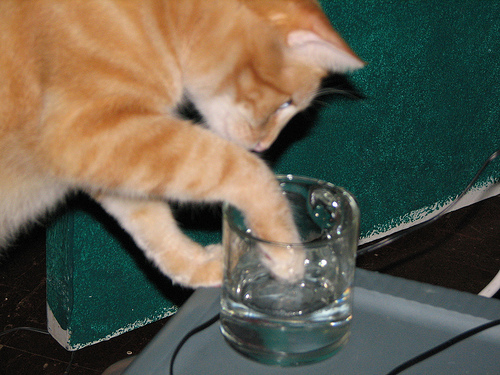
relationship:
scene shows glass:
[5, 7, 495, 372] [221, 174, 356, 364]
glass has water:
[221, 174, 356, 364] [231, 271, 348, 344]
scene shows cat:
[5, 7, 495, 372] [3, 2, 361, 289]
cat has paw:
[3, 2, 361, 289] [260, 239, 310, 286]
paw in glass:
[260, 239, 310, 286] [221, 174, 356, 364]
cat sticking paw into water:
[3, 2, 361, 289] [231, 271, 348, 344]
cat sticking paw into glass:
[3, 2, 361, 289] [221, 174, 356, 364]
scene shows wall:
[5, 7, 495, 372] [355, 16, 499, 234]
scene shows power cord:
[5, 7, 495, 372] [472, 269, 500, 297]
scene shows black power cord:
[5, 7, 495, 372] [168, 148, 496, 374]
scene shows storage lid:
[5, 7, 495, 372] [119, 251, 497, 371]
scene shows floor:
[5, 7, 495, 372] [363, 188, 499, 304]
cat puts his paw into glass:
[3, 2, 361, 289] [221, 174, 356, 364]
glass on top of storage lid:
[221, 174, 356, 364] [119, 251, 497, 371]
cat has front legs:
[3, 2, 361, 289] [84, 118, 308, 286]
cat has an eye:
[3, 2, 361, 289] [276, 98, 295, 111]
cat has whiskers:
[3, 2, 361, 289] [316, 84, 366, 112]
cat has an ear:
[3, 2, 361, 289] [289, 30, 364, 75]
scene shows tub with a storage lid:
[5, 7, 495, 372] [119, 251, 497, 371]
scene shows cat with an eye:
[5, 7, 495, 372] [276, 98, 295, 111]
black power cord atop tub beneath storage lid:
[351, 154, 496, 255] [119, 251, 497, 371]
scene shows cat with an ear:
[5, 7, 495, 372] [289, 30, 364, 75]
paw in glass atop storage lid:
[260, 239, 310, 286] [119, 251, 497, 371]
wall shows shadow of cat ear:
[355, 16, 499, 234] [289, 30, 364, 75]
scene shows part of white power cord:
[5, 7, 495, 372] [472, 269, 500, 297]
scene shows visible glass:
[5, 7, 495, 372] [221, 174, 356, 364]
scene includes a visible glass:
[5, 7, 495, 372] [221, 174, 356, 364]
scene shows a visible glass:
[5, 7, 495, 372] [221, 174, 356, 364]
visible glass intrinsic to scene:
[221, 174, 356, 364] [5, 7, 495, 372]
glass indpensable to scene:
[221, 174, 356, 364] [5, 7, 495, 372]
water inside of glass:
[231, 271, 348, 344] [221, 174, 356, 364]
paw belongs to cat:
[260, 239, 310, 286] [3, 2, 361, 289]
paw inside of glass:
[260, 239, 310, 286] [221, 174, 356, 364]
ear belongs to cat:
[289, 30, 364, 75] [3, 2, 361, 289]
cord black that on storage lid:
[168, 148, 496, 374] [119, 251, 497, 371]